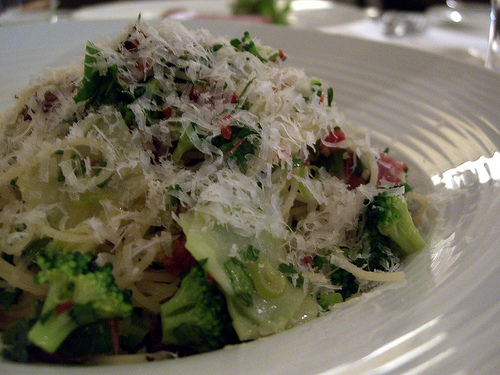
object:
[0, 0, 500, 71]
table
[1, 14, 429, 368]
food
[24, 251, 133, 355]
broccoli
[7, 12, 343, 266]
shreddings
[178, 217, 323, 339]
lettuce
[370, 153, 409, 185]
tomato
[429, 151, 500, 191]
light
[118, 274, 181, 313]
noodles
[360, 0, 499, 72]
glasses